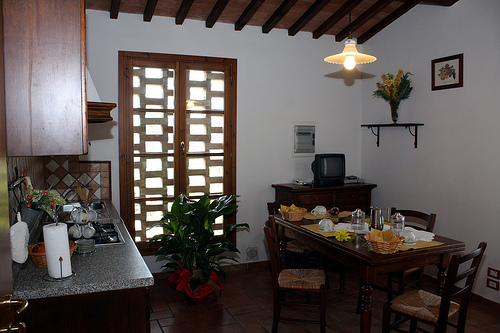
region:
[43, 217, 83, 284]
a roll of paper towels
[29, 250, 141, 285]
the counter appears to be granite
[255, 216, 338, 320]
the chairs have wicker seats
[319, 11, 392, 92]
the overhead light is an interesting shape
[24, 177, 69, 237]
flowers are on the counter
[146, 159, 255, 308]
a house tree stands by the door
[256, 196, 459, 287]
the dining table is set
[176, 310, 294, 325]
the floor is tiled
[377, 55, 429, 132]
a vase of flowers sits on the shelf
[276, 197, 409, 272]
baskets sit at either end of the table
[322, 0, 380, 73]
a ceiling light fixture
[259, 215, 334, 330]
a brown dining chair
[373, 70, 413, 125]
hanging wall flowers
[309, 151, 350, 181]
a small black t.v.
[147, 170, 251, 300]
a large floor plant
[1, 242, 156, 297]
a gray counter top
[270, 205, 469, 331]
a brown kitchen table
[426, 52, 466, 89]
a small picture frame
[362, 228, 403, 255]
a small brown basket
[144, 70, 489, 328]
a dining area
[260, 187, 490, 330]
dining table and chairs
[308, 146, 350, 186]
a television on top of buffet table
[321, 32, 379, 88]
a light fixture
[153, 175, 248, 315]
a pant by the window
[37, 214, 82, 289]
a roll of paper towel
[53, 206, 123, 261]
a stove top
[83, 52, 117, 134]
a part of a vent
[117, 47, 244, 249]
a large window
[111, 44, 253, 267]
a large window with a wooden frame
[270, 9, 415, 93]
light hanging from ceiling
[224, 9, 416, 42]
black rafters on ceiling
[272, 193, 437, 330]
chairs and table in room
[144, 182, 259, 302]
large green plant on floor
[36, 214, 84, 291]
white paper towel on holder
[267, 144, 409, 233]
bureau in corner of room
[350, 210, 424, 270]
basket on corner of table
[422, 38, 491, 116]
framed picture on white wall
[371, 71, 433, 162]
vase of flowers on shelf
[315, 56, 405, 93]
reflection of light fixture on wall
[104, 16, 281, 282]
a tall window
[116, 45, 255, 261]
a window framed in wood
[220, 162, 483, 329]
a dining room table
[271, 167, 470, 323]
a dining room table with placemats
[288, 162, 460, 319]
cups upside down on table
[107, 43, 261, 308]
a plant in fron tof the window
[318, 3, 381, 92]
a light hanging from the ceiling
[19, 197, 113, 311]
a roll of paper towels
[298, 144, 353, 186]
a small black tv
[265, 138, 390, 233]
a tv on a stand